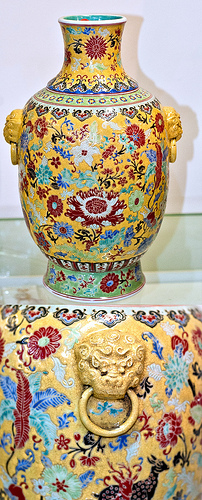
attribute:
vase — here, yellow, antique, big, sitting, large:
[3, 15, 181, 300]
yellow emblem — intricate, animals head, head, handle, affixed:
[168, 107, 181, 165]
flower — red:
[28, 326, 62, 359]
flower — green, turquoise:
[34, 462, 84, 499]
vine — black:
[66, 436, 105, 458]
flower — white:
[70, 143, 102, 168]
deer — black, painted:
[92, 455, 168, 500]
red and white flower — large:
[66, 187, 126, 226]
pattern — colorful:
[30, 87, 155, 106]